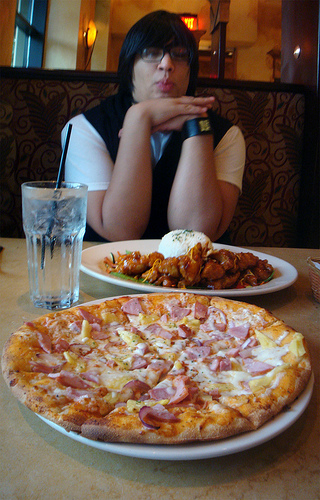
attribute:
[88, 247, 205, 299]
dish — white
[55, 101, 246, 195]
shirt — white